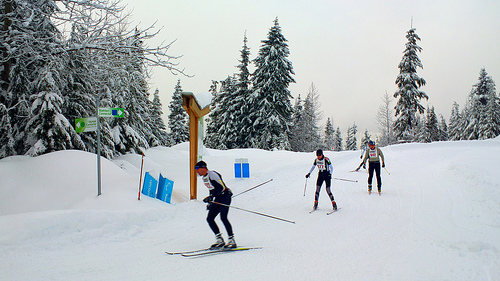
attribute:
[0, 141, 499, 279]
snow — white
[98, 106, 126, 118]
sign — green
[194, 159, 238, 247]
skier — skiing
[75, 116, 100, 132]
sign — green, white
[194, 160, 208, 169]
cap — black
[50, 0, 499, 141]
sky — light grey, hazy, gray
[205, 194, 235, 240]
pants — dark blue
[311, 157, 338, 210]
skier — skiing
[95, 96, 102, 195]
pole — silver, metal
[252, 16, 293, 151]
tree — pine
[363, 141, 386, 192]
skier — skiing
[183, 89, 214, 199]
mail box — wooden, tall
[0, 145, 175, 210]
snow — white